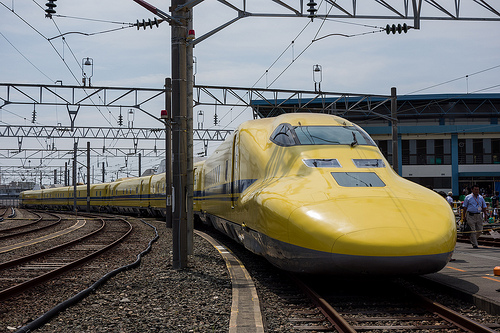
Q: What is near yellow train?
A: Two empty tracks.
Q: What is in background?
A: Building with blue trim.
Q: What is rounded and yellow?
A: Front of train.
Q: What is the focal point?
A: A yellow train.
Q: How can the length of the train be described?
A: Long.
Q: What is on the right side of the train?
A: A building.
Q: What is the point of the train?
A: The nose.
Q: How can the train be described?
A: Yellow and black.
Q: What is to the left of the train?
A: A wooden pole.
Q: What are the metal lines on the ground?
A: Train tracks.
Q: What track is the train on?
A: Right.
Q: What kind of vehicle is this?
A: Train.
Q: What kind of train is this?
A: Long yellow modern train.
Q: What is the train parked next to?
A: Platform.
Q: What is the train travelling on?
A: Train tracks.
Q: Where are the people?
A: Platform.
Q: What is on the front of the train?
A: Four windows.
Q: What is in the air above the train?
A: Power lines.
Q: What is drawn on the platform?
A: Orange lines.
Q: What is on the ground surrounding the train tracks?
A: Gravel and rock.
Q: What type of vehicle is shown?
A: Train.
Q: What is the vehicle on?
A: Tracks.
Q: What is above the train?
A: Wires.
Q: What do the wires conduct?
A: Power.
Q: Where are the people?
A: Right of the train.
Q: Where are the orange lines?
A: On walkway.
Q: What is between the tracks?
A: Gravel.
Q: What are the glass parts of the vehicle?
A: Windows.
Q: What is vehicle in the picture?
A: Train.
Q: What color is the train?
A: Yellow.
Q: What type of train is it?
A: High speed.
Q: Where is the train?
A: Train Station.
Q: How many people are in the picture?
A: 1.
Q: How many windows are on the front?
A: 4.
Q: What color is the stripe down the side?
A: Black.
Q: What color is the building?
A: Blue.